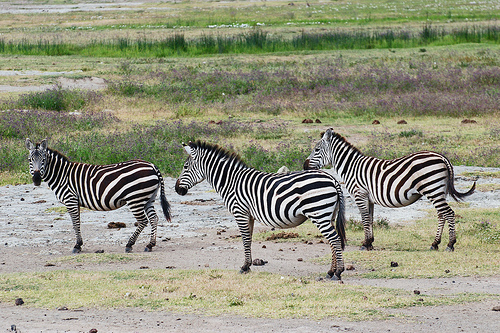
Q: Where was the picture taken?
A: It was taken at the field.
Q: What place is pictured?
A: It is a field.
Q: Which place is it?
A: It is a field.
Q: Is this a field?
A: Yes, it is a field.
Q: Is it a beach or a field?
A: It is a field.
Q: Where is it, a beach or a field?
A: It is a field.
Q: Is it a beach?
A: No, it is a field.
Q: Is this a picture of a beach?
A: No, the picture is showing a field.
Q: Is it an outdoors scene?
A: Yes, it is outdoors.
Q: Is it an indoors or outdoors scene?
A: It is outdoors.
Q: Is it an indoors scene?
A: No, it is outdoors.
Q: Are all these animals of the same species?
A: Yes, all the animals are zebras.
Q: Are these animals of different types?
A: No, all the animals are zebras.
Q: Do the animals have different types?
A: No, all the animals are zebras.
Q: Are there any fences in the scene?
A: No, there are no fences.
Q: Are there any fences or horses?
A: No, there are no fences or horses.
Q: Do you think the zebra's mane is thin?
A: No, the mane is thick.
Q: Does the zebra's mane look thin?
A: No, the mane is thick.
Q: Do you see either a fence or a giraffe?
A: No, there are no fences or giraffes.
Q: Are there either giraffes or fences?
A: No, there are no fences or giraffes.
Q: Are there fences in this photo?
A: No, there are no fences.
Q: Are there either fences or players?
A: No, there are no fences or players.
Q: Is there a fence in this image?
A: No, there are no fences.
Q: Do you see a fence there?
A: No, there are no fences.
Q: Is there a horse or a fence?
A: No, there are no fences or horses.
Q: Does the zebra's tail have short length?
A: No, the tail is long.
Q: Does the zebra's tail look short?
A: No, the tail is long.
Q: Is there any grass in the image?
A: Yes, there is grass.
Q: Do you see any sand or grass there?
A: Yes, there is grass.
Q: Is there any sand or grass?
A: Yes, there is grass.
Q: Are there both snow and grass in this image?
A: No, there is grass but no snow.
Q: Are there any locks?
A: No, there are no locks.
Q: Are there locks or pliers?
A: No, there are no locks or pliers.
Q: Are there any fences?
A: No, there are no fences.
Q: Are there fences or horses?
A: No, there are no fences or horses.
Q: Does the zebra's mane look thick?
A: Yes, the mane is thick.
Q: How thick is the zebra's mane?
A: The mane is thick.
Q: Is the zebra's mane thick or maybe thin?
A: The mane is thick.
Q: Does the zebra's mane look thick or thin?
A: The mane is thick.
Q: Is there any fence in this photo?
A: No, there are no fences.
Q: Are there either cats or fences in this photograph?
A: No, there are no fences or cats.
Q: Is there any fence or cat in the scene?
A: No, there are no fences or cats.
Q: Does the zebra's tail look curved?
A: Yes, the tail is curved.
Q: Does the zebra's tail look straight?
A: No, the tail is curved.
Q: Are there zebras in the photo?
A: Yes, there is a zebra.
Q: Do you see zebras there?
A: Yes, there is a zebra.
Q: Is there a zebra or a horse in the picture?
A: Yes, there is a zebra.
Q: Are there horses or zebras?
A: Yes, there is a zebra.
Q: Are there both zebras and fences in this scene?
A: No, there is a zebra but no fences.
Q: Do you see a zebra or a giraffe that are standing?
A: Yes, the zebra is standing.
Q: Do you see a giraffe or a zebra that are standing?
A: Yes, the zebra is standing.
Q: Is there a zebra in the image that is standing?
A: Yes, there is a zebra that is standing.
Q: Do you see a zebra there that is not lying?
A: Yes, there is a zebra that is standing .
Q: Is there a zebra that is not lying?
A: Yes, there is a zebra that is standing.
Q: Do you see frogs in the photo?
A: No, there are no frogs.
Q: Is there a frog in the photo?
A: No, there are no frogs.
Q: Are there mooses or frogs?
A: No, there are no frogs or mooses.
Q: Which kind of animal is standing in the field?
A: The animal is a zebra.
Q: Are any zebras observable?
A: Yes, there is a zebra.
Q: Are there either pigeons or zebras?
A: Yes, there is a zebra.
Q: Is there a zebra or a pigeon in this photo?
A: Yes, there is a zebra.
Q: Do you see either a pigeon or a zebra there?
A: Yes, there is a zebra.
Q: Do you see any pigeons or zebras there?
A: Yes, there is a zebra.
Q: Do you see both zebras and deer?
A: No, there is a zebra but no deer.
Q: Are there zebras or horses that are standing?
A: Yes, the zebra is standing.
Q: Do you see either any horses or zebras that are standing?
A: Yes, the zebra is standing.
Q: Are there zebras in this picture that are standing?
A: Yes, there is a zebra that is standing.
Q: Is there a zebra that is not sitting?
A: Yes, there is a zebra that is standing.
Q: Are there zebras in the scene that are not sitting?
A: Yes, there is a zebra that is standing.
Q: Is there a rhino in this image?
A: No, there are no rhinos.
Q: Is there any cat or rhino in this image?
A: No, there are no rhinos or cats.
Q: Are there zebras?
A: Yes, there are zebras.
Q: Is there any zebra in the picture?
A: Yes, there are zebras.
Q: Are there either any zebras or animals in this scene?
A: Yes, there are zebras.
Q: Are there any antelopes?
A: No, there are no antelopes.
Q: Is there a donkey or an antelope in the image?
A: No, there are no antelopes or donkeys.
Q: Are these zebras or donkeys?
A: These are zebras.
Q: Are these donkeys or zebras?
A: These are zebras.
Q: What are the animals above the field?
A: The animals are zebras.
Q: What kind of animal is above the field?
A: The animals are zebras.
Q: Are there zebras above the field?
A: Yes, there are zebras above the field.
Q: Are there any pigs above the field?
A: No, there are zebras above the field.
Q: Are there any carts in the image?
A: No, there are no carts.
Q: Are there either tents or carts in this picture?
A: No, there are no carts or tents.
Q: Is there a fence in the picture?
A: No, there are no fences.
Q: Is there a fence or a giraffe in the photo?
A: No, there are no fences or giraffes.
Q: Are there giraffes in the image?
A: No, there are no giraffes.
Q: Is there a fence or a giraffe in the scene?
A: No, there are no giraffes or fences.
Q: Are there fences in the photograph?
A: No, there are no fences.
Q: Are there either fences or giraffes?
A: No, there are no fences or giraffes.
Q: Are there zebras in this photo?
A: Yes, there is a zebra.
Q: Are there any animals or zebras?
A: Yes, there is a zebra.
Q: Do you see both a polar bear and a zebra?
A: No, there is a zebra but no polar bears.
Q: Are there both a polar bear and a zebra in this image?
A: No, there is a zebra but no polar bears.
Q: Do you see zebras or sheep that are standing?
A: Yes, the zebra is standing.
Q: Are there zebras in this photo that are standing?
A: Yes, there is a zebra that is standing.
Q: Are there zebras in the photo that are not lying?
A: Yes, there is a zebra that is standing.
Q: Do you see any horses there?
A: No, there are no horses.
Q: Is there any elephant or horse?
A: No, there are no horses or elephants.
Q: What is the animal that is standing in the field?
A: The animal is a zebra.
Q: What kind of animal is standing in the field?
A: The animal is a zebra.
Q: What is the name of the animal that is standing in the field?
A: The animal is a zebra.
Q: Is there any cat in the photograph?
A: No, there are no cats.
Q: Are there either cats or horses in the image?
A: No, there are no cats or horses.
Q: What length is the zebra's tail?
A: The tail is long.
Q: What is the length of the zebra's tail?
A: The tail is long.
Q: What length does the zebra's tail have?
A: The tail has long length.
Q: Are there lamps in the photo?
A: No, there are no lamps.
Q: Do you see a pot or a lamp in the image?
A: No, there are no lamps or pots.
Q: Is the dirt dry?
A: Yes, the dirt is dry.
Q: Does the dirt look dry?
A: Yes, the dirt is dry.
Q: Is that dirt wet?
A: No, the dirt is dry.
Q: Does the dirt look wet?
A: No, the dirt is dry.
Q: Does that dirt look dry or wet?
A: The dirt is dry.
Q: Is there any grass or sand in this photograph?
A: Yes, there is grass.